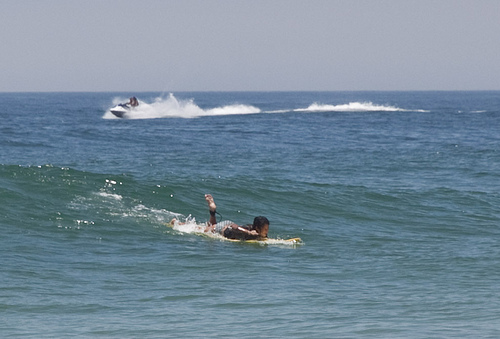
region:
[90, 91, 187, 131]
jet ski on the water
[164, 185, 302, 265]
peson paddling on surfboard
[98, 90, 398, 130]
jet ski and water spray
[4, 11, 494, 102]
sky and water horizen line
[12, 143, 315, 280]
wave behind person on surfboard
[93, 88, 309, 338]
two people in the ocean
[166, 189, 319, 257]
dark haired person on surfboard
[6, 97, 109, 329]
blue and green shades of ocean water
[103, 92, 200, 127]
person on a jet ski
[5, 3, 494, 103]
gray sky above water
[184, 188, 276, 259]
surfer on board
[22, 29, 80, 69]
white clouds in blue sky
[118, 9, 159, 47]
white clouds in blue sky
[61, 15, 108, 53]
white clouds in blue sky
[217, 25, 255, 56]
white clouds in blue sky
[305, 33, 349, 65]
white clouds in blue sky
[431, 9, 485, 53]
white clouds in blue sky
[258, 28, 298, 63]
white clouds in blue sky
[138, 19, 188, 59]
white clouds in blue sky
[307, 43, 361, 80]
white clouds in blue sky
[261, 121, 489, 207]
Water is blue color.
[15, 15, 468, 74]
Sky is blue color.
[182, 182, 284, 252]
Man is surfing in water.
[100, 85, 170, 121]
Boat is white color.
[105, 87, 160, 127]
One man is riding the boat.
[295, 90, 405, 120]
Waves are white color.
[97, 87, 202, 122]
Water is splashing.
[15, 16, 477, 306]
Day time picture.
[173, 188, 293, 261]
Man is lying on surfing board.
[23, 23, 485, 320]
Picture is taken in beach.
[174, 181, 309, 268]
surfer lying on board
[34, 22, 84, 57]
white clouds in blue sky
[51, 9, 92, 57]
white clouds in blue sky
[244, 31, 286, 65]
white clouds in blue sky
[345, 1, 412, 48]
white clouds in blue sky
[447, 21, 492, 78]
white clouds in blue sky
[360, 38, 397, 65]
white clouds in blue sky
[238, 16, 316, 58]
white clouds in blue sky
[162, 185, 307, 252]
a surfer in the water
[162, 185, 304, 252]
man on a surfboard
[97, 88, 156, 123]
person on a motorbike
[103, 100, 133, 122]
motorbike is color white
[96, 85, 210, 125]
motorbike makes a big splash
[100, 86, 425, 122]
splashed behind a motorbike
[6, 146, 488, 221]
a wave is rolling in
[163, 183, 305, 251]
left leg of boy is up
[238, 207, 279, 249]
boy has black hair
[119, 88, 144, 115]
man wears a helmet